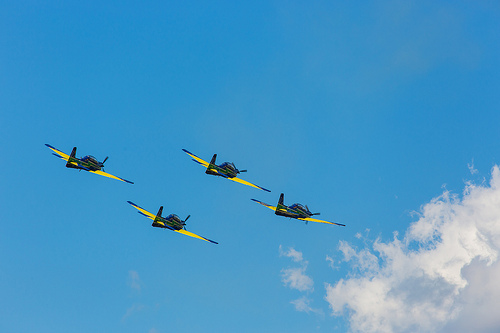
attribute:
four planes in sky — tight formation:
[39, 89, 376, 261]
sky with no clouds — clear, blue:
[265, 20, 455, 132]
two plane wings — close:
[224, 162, 300, 229]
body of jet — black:
[71, 146, 108, 187]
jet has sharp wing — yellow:
[166, 137, 220, 185]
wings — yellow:
[125, 200, 225, 248]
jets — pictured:
[32, 124, 348, 252]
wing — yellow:
[174, 138, 207, 168]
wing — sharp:
[161, 223, 219, 249]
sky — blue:
[3, 2, 499, 331]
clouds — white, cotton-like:
[274, 160, 495, 322]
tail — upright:
[205, 149, 218, 177]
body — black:
[149, 208, 184, 233]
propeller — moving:
[226, 154, 247, 179]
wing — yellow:
[52, 135, 342, 248]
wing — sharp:
[54, 130, 352, 240]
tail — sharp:
[198, 152, 220, 186]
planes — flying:
[39, 124, 345, 282]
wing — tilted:
[174, 139, 208, 173]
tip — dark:
[252, 180, 280, 203]